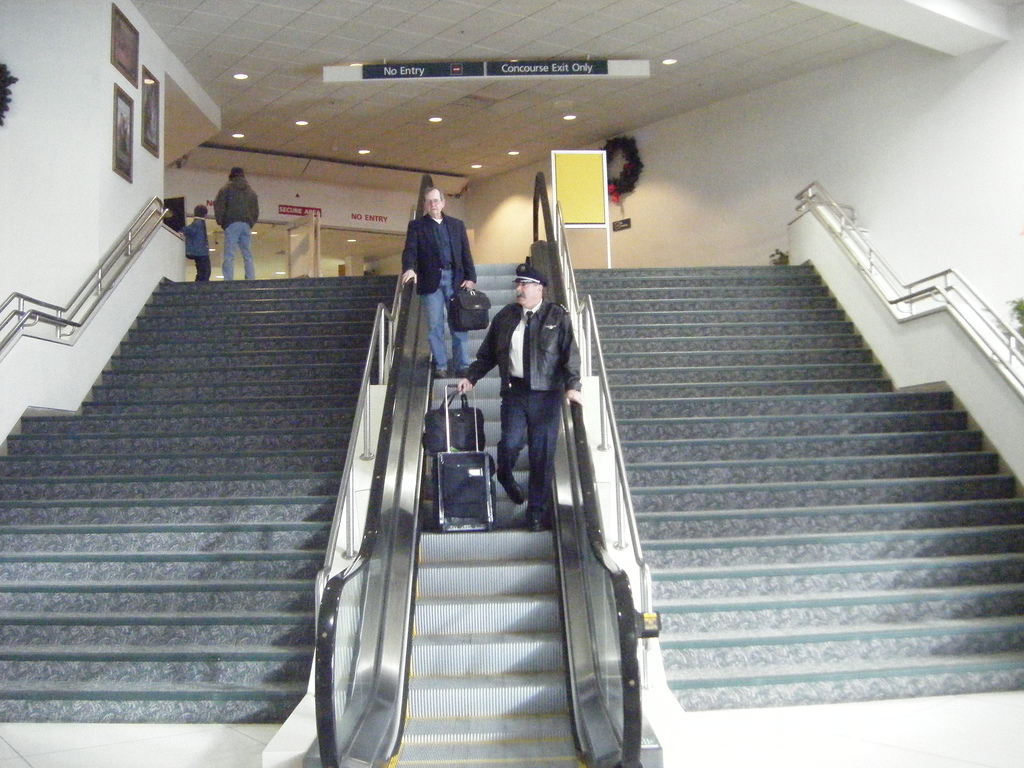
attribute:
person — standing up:
[388, 167, 499, 382]